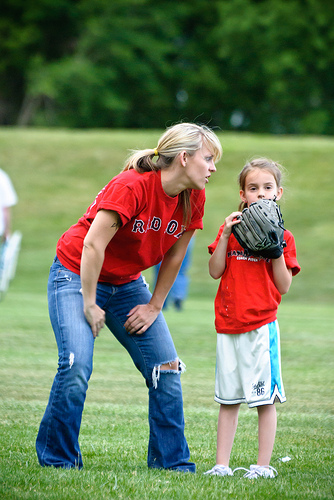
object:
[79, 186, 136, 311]
arms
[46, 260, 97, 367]
thighs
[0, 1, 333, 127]
branches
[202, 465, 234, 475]
tennis shoe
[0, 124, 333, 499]
grass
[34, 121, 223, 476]
woman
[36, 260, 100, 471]
legs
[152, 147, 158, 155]
hairband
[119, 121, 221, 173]
hair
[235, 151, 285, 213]
hair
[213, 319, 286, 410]
short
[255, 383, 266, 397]
86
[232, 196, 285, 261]
glove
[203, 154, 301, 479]
girl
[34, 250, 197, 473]
pants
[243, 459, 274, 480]
shoe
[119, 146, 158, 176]
ponytail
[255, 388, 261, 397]
number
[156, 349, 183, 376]
knee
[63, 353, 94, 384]
knee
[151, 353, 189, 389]
tear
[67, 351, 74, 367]
tear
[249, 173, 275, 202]
look